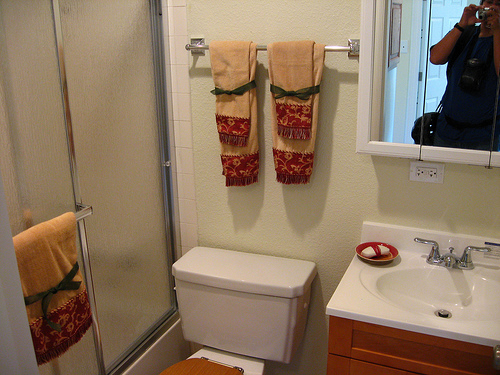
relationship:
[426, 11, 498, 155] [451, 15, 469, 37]
man wearing watch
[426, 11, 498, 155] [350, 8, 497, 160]
woman in mirror